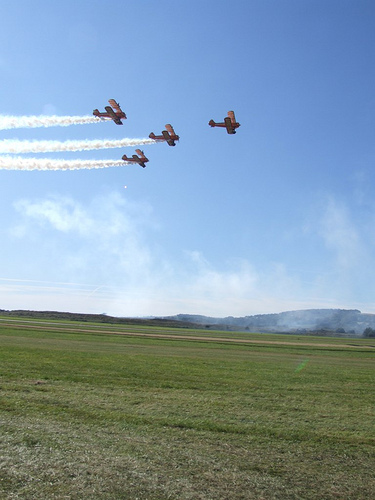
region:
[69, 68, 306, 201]
four planes flying in formation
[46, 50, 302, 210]
The planes are biplanes.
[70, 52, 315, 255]
the biplanes have fixed wings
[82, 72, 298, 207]
the biplanes are red and white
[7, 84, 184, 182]
only these three have smoke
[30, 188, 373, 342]
there is smoke in the air close to the ground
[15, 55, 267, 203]
the planes are flying at a low altitude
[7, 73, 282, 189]
the planes are flying over an open field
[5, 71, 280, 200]
four biplanes flying over green grass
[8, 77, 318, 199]
four red and white biplanes in the sky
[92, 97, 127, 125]
a plane in flight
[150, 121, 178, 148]
a plane in flight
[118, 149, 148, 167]
a plane in flight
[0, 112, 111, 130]
a smoke trail left by a plane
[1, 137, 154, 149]
a smoke trail left by a plane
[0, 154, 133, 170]
a smoke trail left by a plane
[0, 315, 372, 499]
a wide open stretch of grass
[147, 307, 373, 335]
a hill in the distance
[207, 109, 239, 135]
a two winged plane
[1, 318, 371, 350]
a large stretch of dirt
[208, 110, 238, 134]
a biplane in flight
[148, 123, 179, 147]
a biplane in flight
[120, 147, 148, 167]
a biplane in flight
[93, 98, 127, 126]
a biplane in flight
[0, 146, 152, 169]
airplane an airplane skywriting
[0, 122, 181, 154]
airplane an airplane skywriting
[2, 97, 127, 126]
airplane an airplane skywriting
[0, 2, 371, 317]
a cloudy blue sky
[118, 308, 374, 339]
a hilly area in distance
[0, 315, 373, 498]
a green grassy field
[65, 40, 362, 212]
airplanes in teh sky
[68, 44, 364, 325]
airplanes in the air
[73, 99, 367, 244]
planes in the sky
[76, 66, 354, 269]
planes in the air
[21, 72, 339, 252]
planes creating smoke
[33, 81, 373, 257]
planes creating a line of smoke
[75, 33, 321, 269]
airplanes making smoke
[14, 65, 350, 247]
planes making a line of white smoke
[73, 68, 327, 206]
four airplanes in the air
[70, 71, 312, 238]
four airplane sin the sky